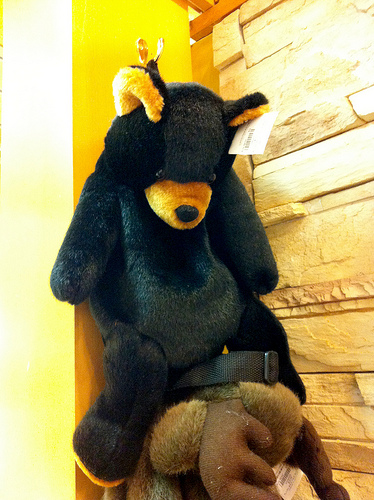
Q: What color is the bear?
A: Black and brown.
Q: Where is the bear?
A: On the hook.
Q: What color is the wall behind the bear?
A: Yellow.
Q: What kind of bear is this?
A: Teddy bear.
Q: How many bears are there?
A: One.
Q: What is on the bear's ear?
A: A tag.